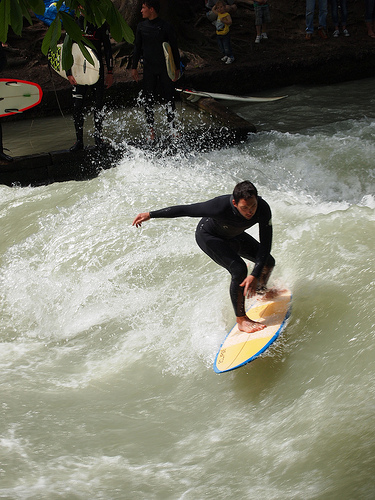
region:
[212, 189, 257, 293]
Man wearing wet suit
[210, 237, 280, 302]
Wet suit is black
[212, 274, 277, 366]
Man standing on surfboard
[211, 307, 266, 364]
Surfboard is yellow and blue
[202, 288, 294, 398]
Surfboard is in water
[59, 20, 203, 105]
Men holding surfboards on side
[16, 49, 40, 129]
White surfboard with red edges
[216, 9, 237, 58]
Little kid wearing yellow shirt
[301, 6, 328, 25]
Person wearing blue jeans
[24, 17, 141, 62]
Green leaves on tree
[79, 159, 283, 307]
Man in a black wet suit.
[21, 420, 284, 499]
Gray and white water.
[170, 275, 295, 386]
Yellow and blue surf board.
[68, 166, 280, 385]
Man riding a surf board.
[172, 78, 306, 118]
White and red surfboard.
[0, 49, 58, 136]
Bottom of a red and white surfboard.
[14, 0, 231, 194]
Two people standing by waters edge.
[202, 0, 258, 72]
Toddler in yellow shirt.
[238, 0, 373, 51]
A group of legs and feet.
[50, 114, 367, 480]
Man in wet suit surfing.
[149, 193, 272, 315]
a man is wearing a black wet suit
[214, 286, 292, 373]
the mans surfboard is yellow with a blue trim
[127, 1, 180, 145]
a surfer is waiting on the side of the pool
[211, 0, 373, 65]
spectators watching the sufers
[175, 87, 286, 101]
a white and red surfboard stored on the deck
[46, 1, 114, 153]
a surfer standing behind a tree branch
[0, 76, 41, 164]
another surfer standing on the side holding a white surfboard with red trim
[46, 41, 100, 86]
a white surfboard with a green abstract design on the top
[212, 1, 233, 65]
a child in a yellow shirt stands on the side watching the surfers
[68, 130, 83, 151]
the surfer is wearing surfing booties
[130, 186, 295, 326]
A man in a black wet suit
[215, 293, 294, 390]
A yellow and blue surf board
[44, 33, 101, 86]
A green and white surf board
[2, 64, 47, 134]
An orange and white surf board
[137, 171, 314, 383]
A man surfing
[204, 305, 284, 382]
A foot on a surf board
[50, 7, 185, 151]
Two people holding surf boards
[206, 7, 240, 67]
A child in a yellow shirt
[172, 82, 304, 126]
A surf board on the ground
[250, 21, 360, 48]
The feet of three people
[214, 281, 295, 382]
a yellow and blue surf board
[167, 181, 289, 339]
a man wearing a black wet suit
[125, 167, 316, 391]
a man on a surf board in the water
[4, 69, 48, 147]
a red and white surf board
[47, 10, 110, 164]
a person holding a surf board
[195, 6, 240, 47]
a young girl in a yellow shirt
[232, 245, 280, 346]
a person not wearing shoes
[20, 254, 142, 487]
a body of water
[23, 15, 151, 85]
large green leaves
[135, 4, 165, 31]
a man turning his head